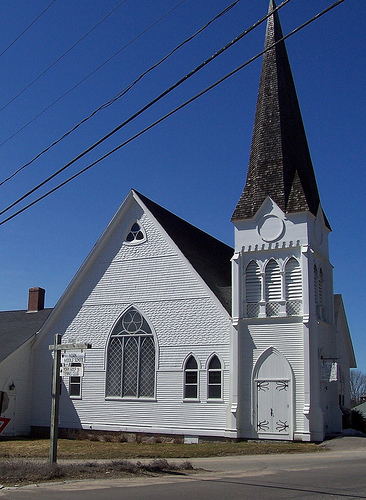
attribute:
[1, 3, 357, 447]
church — white, victorian looking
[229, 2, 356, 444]
steeple — tall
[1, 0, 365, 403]
sky — blue, bright blue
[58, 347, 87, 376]
sign — street sign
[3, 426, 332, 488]
grass — brown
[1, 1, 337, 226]
power lines — for telephone, electrical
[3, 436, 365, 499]
road — gray, brown, pavement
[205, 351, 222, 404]
windows — shaped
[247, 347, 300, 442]
door — shut, closed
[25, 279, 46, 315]
chimney — brick